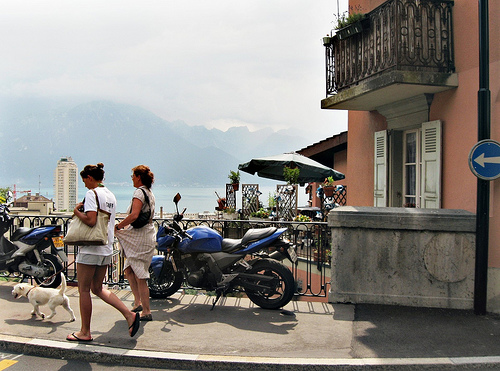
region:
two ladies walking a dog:
[10, 158, 172, 346]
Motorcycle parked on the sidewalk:
[149, 192, 314, 324]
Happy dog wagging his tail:
[6, 274, 81, 326]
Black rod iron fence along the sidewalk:
[108, 216, 322, 304]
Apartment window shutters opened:
[375, 124, 445, 211]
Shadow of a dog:
[3, 310, 78, 337]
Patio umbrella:
[231, 147, 348, 194]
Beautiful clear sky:
[0, 110, 314, 183]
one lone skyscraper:
[44, 151, 82, 228]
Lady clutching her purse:
[59, 162, 139, 350]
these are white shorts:
[67, 242, 127, 274]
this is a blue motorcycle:
[116, 202, 315, 333]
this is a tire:
[237, 257, 302, 309]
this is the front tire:
[134, 246, 194, 298]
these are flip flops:
[61, 305, 154, 360]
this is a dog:
[8, 262, 83, 332]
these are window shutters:
[367, 117, 464, 229]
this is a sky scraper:
[40, 136, 91, 222]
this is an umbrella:
[233, 123, 341, 190]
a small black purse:
[123, 194, 161, 234]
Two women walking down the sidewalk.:
[5, 142, 210, 349]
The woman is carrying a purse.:
[55, 150, 125, 292]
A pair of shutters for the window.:
[365, 105, 450, 220]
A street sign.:
[455, 130, 495, 191]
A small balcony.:
[310, 0, 460, 125]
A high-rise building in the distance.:
[45, 150, 81, 216]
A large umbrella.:
[225, 145, 341, 206]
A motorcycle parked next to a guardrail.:
[145, 215, 300, 325]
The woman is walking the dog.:
[0, 161, 175, 321]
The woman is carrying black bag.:
[121, 183, 161, 238]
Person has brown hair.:
[76, 159, 105, 176]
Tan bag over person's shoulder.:
[55, 188, 130, 257]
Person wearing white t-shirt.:
[98, 207, 139, 224]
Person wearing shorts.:
[69, 245, 123, 287]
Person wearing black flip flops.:
[47, 310, 121, 365]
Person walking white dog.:
[18, 256, 124, 303]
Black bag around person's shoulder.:
[116, 177, 175, 247]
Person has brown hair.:
[133, 165, 146, 175]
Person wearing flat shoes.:
[133, 300, 164, 333]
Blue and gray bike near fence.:
[166, 223, 273, 283]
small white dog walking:
[8, 275, 76, 322]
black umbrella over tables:
[236, 149, 346, 182]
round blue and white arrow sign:
[466, 137, 498, 180]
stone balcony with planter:
[319, 0, 456, 110]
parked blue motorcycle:
[147, 191, 299, 311]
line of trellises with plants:
[220, 182, 348, 251]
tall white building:
[53, 154, 78, 212]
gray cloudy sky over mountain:
[1, 0, 345, 127]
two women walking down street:
[60, 158, 160, 344]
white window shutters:
[370, 119, 442, 206]